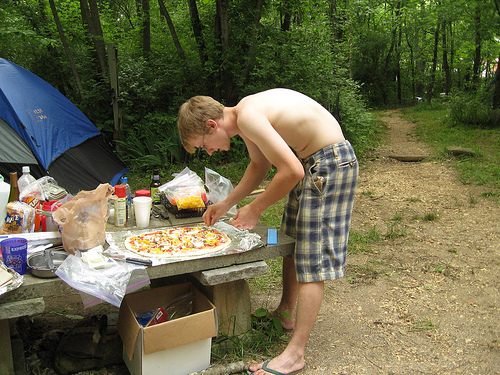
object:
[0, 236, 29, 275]
cup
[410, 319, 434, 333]
grass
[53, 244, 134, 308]
bags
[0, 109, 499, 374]
ground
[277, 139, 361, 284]
pants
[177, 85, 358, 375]
man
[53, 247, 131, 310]
plastic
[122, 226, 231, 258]
pizza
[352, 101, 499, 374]
path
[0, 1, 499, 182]
woods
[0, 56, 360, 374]
campsite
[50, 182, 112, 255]
bag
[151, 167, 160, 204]
bottle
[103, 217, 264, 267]
aluminum foil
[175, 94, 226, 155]
cut hair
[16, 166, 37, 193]
bottle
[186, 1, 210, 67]
branch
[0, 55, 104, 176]
tent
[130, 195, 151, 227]
cup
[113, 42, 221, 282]
box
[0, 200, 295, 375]
table